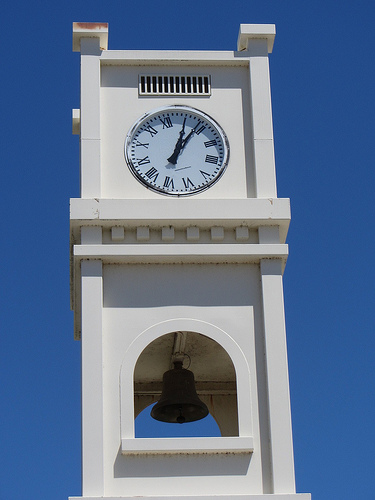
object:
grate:
[138, 72, 212, 95]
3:
[203, 138, 219, 148]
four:
[204, 153, 218, 163]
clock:
[123, 103, 230, 197]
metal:
[171, 381, 187, 399]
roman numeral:
[199, 170, 211, 179]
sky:
[0, 0, 374, 498]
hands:
[168, 114, 188, 164]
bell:
[149, 360, 209, 422]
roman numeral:
[159, 114, 174, 129]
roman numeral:
[146, 165, 158, 182]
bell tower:
[68, 21, 311, 499]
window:
[132, 329, 238, 438]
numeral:
[203, 138, 217, 146]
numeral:
[136, 155, 150, 164]